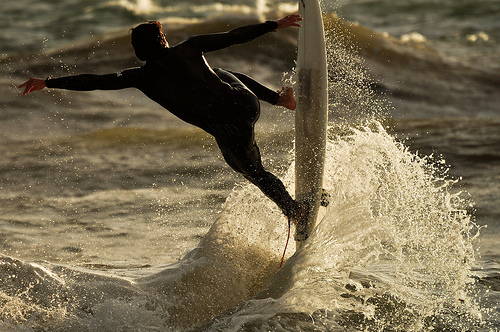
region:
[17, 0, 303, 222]
a surfer in a black wetsuit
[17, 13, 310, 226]
a male surfer wearing a black wetsuit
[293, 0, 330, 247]
a white surfboard in the air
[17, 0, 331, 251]
a surfboard vertically on the wave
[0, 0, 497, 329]
a white surfboard lifted in the air by an ocean wave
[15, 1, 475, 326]
a man in a black wetsuit surfing on the ocean water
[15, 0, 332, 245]
a surfer in black surfing on a white surfboard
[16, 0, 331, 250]
a surfer about to fall in the ocean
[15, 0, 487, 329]
a big wave lifting a surfer on a surfboard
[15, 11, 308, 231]
a man balancing on a vertical surfboard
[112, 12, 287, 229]
a man in a black wet suite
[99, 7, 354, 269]
a man in a black wet suit surfing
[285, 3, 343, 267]
a white surfboard in the water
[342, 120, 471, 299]
the splashes of water from a surfboard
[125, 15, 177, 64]
a head of a man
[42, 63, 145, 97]
the arm of a man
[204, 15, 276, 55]
the arm of a man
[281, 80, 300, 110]
the bare foot of a man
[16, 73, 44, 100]
the hand of a man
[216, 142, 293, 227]
the leg of a man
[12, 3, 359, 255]
a surfer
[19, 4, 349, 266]
a man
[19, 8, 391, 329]
a man is surfing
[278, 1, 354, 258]
the surfboard is vertical in the air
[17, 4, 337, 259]
the man is in the air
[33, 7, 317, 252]
the surfer is wearing black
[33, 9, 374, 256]
the surfer is trying to control the surfboard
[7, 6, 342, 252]
the man is wearing a black wet suit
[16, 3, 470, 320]
the man surfs on the ocean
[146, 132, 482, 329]
water sprays all around the surfboard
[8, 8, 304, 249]
man wearing dark wetsuit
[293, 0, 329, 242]
vertically placed white surfboard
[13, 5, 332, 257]
man vertically placed on surfboard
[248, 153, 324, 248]
man's foot on surfboard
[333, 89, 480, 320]
white seaspray in ocean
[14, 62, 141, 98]
man's left arm extended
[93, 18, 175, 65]
back of man's head with ocean in background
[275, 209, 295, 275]
red surfboard tethercord attached to foot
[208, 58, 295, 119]
man's leg crouched over surfboard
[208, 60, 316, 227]
two male legs on surfboard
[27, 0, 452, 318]
the man is surfing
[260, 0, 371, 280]
the surfboard is white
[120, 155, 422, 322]
the wave is white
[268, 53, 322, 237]
the man is bare foot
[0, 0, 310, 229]
the man is wearing a wetsuit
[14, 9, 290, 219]
the suit is black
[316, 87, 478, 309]
the water is splashing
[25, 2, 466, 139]
the water is rough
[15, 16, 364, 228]
the man`s arms are out